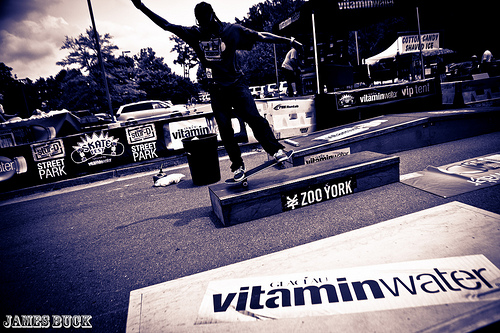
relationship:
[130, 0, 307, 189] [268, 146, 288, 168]
man wearing sneaker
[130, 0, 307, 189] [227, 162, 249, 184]
man wearing sneaker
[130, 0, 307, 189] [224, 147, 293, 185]
man using skate board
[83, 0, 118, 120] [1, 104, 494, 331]
post on road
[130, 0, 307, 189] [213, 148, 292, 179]
man on skateboard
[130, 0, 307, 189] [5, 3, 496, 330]
man in area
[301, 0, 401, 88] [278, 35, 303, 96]
tent with people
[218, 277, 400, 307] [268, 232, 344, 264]
logo on ground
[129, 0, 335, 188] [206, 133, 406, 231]
man on ramp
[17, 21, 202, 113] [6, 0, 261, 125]
trees in background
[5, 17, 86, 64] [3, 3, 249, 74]
clouds in sky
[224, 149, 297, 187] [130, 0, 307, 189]
skate board under man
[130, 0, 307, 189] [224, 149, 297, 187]
man on skate board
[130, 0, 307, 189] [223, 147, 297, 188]
man doing a trick on skateboard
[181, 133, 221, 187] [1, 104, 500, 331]
bin in road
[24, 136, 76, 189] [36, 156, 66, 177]
banner with words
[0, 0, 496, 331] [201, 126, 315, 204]
area to skateboard